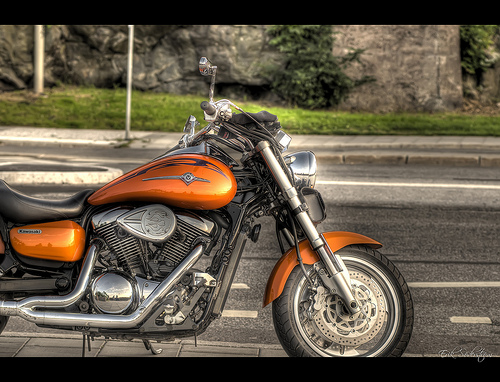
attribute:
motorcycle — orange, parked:
[1, 47, 415, 358]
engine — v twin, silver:
[85, 206, 222, 288]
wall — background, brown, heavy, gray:
[3, 26, 500, 112]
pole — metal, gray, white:
[121, 25, 135, 143]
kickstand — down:
[139, 336, 165, 355]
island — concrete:
[1, 152, 125, 191]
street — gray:
[2, 138, 500, 360]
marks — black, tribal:
[87, 153, 228, 184]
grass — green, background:
[1, 81, 500, 146]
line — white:
[409, 272, 499, 293]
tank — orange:
[82, 151, 238, 216]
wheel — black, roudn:
[269, 243, 417, 356]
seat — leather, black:
[0, 175, 94, 228]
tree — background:
[259, 25, 372, 117]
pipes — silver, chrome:
[0, 240, 207, 334]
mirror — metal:
[193, 57, 221, 102]